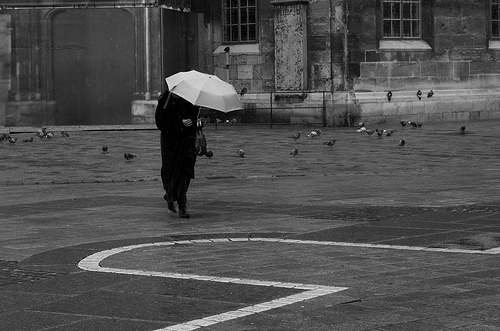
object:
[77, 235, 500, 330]
white line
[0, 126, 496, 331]
road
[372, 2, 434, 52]
window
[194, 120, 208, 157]
bag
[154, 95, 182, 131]
arm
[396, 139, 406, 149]
pigeon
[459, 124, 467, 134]
pigeon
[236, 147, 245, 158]
pigeon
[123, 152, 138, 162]
pigeon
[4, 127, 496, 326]
ground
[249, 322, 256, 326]
bird poop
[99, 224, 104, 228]
bird poop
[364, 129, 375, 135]
pigeons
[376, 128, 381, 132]
pigeons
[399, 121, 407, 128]
pigeons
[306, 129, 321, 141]
pigeons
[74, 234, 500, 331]
line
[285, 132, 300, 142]
pigeons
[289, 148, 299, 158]
birds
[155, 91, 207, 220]
person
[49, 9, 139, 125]
metal door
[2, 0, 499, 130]
build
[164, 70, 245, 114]
umbrella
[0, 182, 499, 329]
walkway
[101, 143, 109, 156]
pigeons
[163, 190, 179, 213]
feet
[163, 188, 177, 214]
boots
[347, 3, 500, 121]
wall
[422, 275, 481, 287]
stones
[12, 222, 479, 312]
rain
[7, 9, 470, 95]
rain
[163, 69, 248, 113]
wet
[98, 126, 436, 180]
food